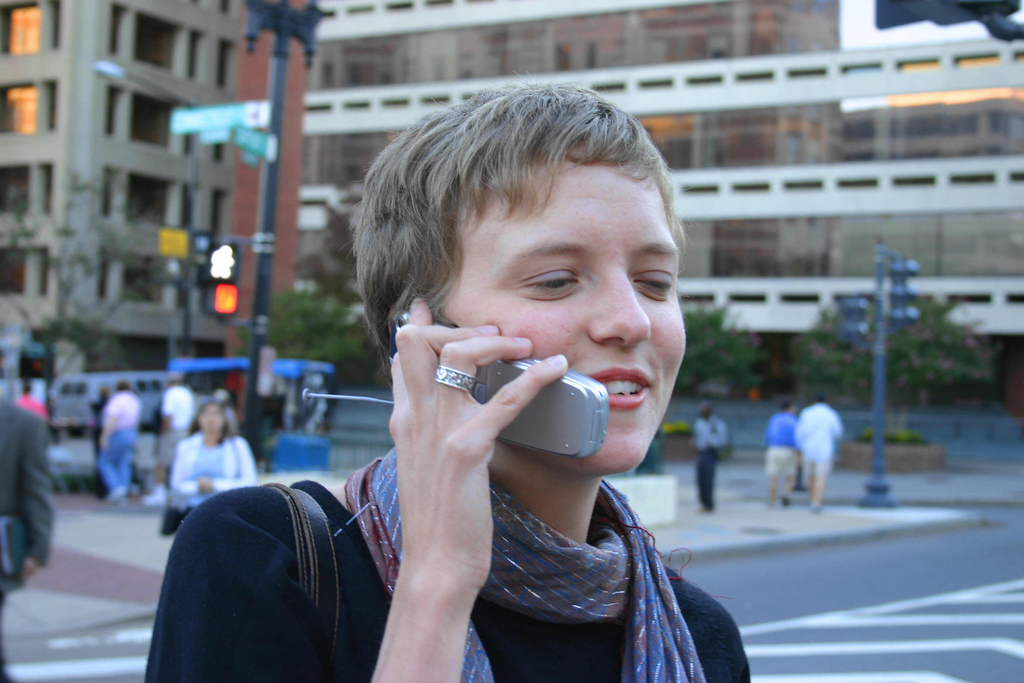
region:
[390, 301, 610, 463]
cell phone is silver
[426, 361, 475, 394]
ring is on the finger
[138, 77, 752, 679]
lady is on the phone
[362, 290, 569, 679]
hand is holding the phone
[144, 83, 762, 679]
lady wearing scarf around her neck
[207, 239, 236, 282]
digital walking man is white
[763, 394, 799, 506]
person wearing blue shirt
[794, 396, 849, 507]
person wearing long sleeves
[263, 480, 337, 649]
strap is on the ladies shoulder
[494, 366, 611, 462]
the bottom of a flip cellphone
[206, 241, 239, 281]
an ok to walk sign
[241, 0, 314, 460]
a light pole on the side of the street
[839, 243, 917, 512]
a black pole on the street corner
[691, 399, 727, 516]
a man in a grey shirt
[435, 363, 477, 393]
a silver ring on a woman's finger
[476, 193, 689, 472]
The face of a lady on the phone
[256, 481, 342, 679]
the strap of a bag or purse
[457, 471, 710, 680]
a scarf that is being worn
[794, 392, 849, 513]
a man in a light blue shirt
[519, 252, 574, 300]
eye of the woman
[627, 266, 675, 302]
eye of the woman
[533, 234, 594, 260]
eyebrow of the woman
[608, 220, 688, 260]
eyebrow of the woman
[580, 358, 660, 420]
mouth of the woman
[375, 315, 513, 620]
hand of the woman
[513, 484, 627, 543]
neck of the woman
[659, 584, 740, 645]
shoulder of the woman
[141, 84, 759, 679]
Woman talking on cell phone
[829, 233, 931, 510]
Street lamp on sidewalk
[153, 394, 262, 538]
Woman wearing a whtie cardigan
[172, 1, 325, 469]
Street post on sidewalk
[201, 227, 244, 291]
Walk sign attached to pole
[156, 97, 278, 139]
Street sign attached to pole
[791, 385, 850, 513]
Person in a white shirt on sidewalk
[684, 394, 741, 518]
Man standing on sidewalk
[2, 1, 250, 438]
Large light grey building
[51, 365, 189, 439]
Grey bus on road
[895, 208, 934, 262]
window on the building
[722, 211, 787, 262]
window on the building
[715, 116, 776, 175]
window on the building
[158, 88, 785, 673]
Woman holding cell phone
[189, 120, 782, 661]
Woman holding silver phone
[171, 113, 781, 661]
Woman holding small phone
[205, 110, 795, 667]
Woman with short hair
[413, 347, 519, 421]
Ring on woman's hand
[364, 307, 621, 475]
Mobile phone in woman's hand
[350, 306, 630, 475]
Small phone in woman's hand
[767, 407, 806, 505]
a person in a blue shirt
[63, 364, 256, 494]
people walking on the sidewalk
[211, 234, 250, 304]
a street walking sign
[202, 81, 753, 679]
a woman on a phone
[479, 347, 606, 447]
the cell phone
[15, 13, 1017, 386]
tall buildings behind the street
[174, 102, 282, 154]
a greet street sign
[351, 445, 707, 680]
a scarf on the woman